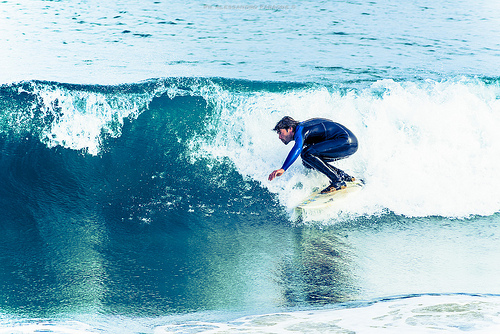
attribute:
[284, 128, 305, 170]
arm — left arm , forward to help with balance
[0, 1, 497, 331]
water — beautiful, turquoise, blue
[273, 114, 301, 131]
dark hair — collar length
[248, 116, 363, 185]
wetsuit — dark blue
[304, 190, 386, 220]
surfboard — beige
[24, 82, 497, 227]
crest — white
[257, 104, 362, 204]
suit — blue 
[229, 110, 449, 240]
person — surfing